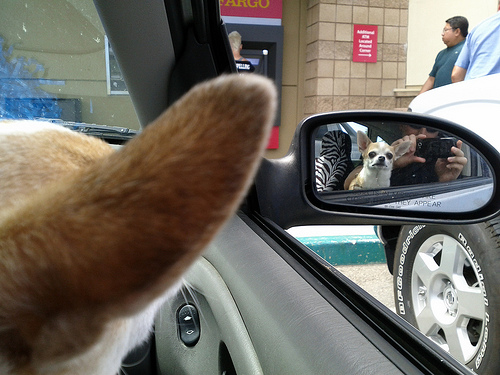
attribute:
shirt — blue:
[429, 43, 467, 88]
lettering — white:
[354, 25, 375, 56]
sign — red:
[349, 22, 381, 64]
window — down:
[190, 42, 493, 362]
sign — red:
[357, 27, 380, 65]